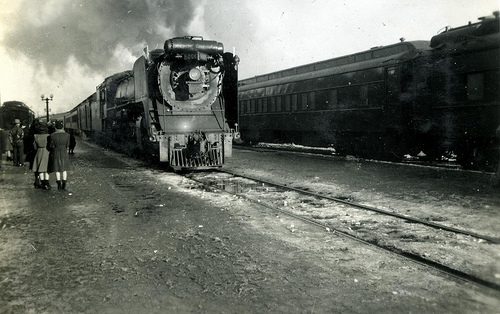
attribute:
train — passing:
[32, 36, 238, 171]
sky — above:
[0, 1, 497, 116]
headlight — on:
[156, 130, 238, 165]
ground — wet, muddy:
[9, 212, 319, 311]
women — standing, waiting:
[30, 119, 74, 194]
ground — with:
[18, 188, 176, 264]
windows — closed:
[240, 79, 387, 116]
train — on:
[64, 37, 276, 182]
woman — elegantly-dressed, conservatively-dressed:
[9, 111, 71, 203]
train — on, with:
[52, 28, 245, 178]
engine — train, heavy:
[96, 32, 241, 169]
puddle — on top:
[191, 171, 274, 196]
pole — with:
[37, 91, 56, 131]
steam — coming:
[5, 1, 200, 41]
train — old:
[47, 9, 339, 215]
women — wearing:
[22, 113, 99, 195]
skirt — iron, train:
[168, 137, 225, 171]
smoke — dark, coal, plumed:
[2, 2, 217, 89]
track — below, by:
[266, 173, 443, 271]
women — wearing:
[28, 122, 75, 189]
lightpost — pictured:
[21, 83, 68, 122]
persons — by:
[53, 119, 79, 187]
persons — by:
[32, 117, 49, 184]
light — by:
[179, 67, 208, 90]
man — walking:
[12, 117, 22, 169]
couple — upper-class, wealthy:
[24, 119, 80, 195]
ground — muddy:
[184, 160, 496, 291]